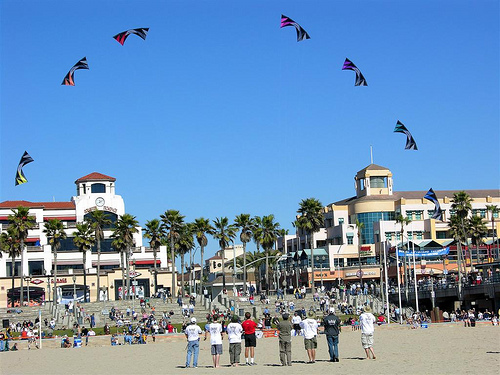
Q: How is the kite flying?
A: Wind.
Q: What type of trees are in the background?
A: Palm tree.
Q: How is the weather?
A: Sunny.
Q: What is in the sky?
A: Flags.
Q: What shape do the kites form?
A: Semicircle.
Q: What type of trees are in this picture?
A: Palm Trees.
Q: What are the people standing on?
A: Sand.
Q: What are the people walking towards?
A: An outdoor mall.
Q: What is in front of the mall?
A: Stair.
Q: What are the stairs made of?
A: Concrete.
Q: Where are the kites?
A: In the sky.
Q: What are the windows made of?
A: Glass.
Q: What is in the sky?
A: Kites.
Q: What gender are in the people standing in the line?
A: Male.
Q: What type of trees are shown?
A: Palm trees.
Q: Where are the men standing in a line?
A: In the sand.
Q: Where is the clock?
A: On the left building.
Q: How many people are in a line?
A: 8.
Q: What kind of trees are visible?
A: Palm trees.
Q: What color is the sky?
A: Blue.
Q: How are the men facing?
A: Towards the buildings.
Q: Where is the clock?
A: On the left building.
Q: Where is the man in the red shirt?
A: Fourth from left in line.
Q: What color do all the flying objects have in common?
A: Black.